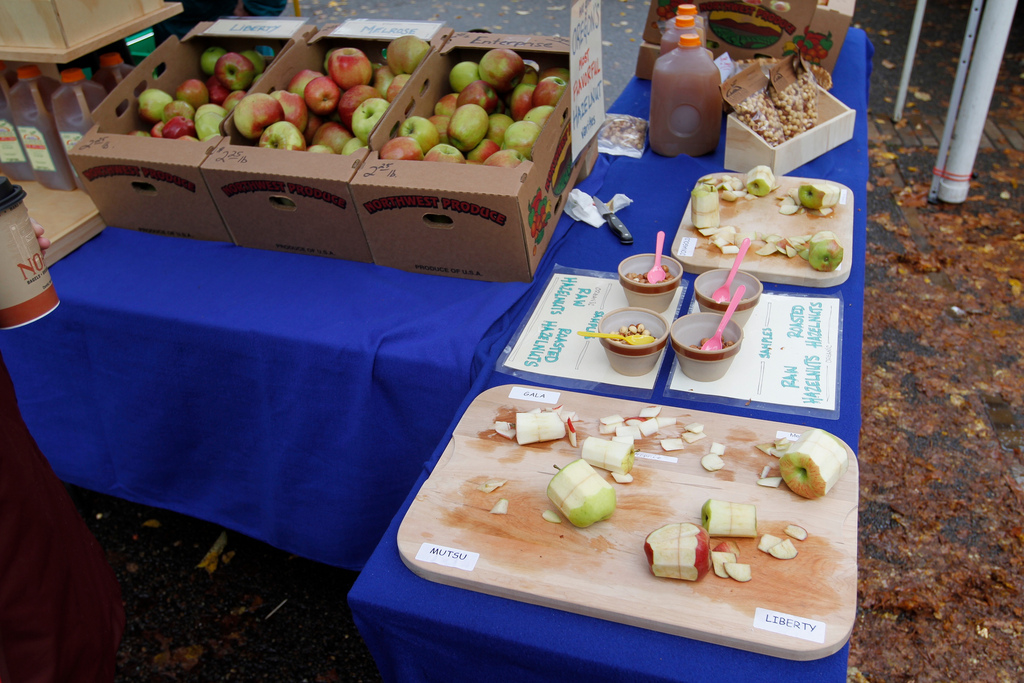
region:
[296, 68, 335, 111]
red and green apple in a box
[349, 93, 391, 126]
red and green apple in a box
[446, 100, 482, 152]
red and green apple in a box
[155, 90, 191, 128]
red and green apple in a box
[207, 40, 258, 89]
red and green apple in a box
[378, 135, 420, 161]
red and green apple in a box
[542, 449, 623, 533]
Green apple on the table.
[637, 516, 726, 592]
Red apple on the table.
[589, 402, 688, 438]
Chopped apples on the table.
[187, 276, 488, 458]
Blue cloth covering the table.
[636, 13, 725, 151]
Jugs of apple cider.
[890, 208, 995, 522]
Leaves covering the ground.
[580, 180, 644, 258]
Knife on the table.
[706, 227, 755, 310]
Pink spoon in the bowl.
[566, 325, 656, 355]
Yellow spoon in the bowl.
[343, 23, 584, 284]
a box of apples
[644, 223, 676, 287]
a pink spoon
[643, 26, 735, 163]
a jug with an orange lid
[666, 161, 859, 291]
green apples on a cutting board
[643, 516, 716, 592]
a red and white apple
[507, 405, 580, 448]
an apple core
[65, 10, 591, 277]
boxes of apples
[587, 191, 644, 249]
a knife with black handle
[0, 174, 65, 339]
a cup on the table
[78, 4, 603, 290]
Brown boxes.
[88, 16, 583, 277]
Three boxes of apples in them.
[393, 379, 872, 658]
A wooden cutting board.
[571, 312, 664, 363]
A yellow spoon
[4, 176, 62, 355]
A coffee cup.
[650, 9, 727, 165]
Jugs of Apple cider.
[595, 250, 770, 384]
Four bowls with spoons.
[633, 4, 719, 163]
Jugs of cider for sale.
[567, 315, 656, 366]
Yellow spoon in a bowl.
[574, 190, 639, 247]
Black handled knife on the table.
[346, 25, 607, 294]
cardboard box of red and green apples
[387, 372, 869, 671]
wooden cutting board with sliced apples on it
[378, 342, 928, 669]
this is a cutting board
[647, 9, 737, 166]
jugs of apple cider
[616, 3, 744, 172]
jugs of apple juice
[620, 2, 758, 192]
freshly pressed apple juice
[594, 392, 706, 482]
sliced apples on a cutting board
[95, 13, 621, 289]
there are apples in a cardboard box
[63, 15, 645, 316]
the boxes are made of cardboard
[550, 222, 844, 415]
there are pink plastic spoons and a yellow spoon in the cups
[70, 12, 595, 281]
Three cardboard boxes filled with apples.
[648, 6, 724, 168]
Three gallons of apple cider.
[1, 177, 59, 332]
Brown and beige coffee cup with a black lid.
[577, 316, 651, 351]
Yellow plastic spoon in a small bowl.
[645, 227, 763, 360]
Three pink plastic spoons.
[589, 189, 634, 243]
Small paring knife with black handles.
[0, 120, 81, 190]
Three yellow labels on quarts of cider.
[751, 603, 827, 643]
The word 'Liberty' on white paper.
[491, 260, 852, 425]
Two white sheets of paper in plastic.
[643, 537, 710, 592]
an apple on display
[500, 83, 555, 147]
an apple on display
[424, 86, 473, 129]
an apple on display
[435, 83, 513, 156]
an apple on display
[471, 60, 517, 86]
an apple on display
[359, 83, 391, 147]
an apple on display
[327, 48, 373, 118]
an apple on display